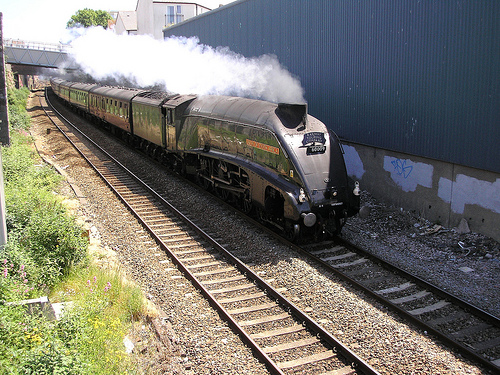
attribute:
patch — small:
[62, 314, 96, 352]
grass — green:
[8, 92, 26, 127]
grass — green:
[3, 147, 46, 200]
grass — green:
[8, 180, 75, 272]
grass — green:
[52, 286, 120, 373]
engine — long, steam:
[39, 60, 345, 240]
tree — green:
[67, 6, 110, 31]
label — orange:
[246, 137, 280, 156]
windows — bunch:
[89, 93, 130, 120]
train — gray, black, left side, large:
[50, 75, 361, 247]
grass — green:
[7, 320, 56, 354]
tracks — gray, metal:
[193, 219, 455, 372]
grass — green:
[68, 277, 142, 342]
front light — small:
[278, 189, 366, 213]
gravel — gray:
[31, 89, 496, 374]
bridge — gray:
[4, 40, 70, 89]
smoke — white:
[67, 22, 319, 114]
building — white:
[132, 1, 211, 39]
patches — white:
[343, 142, 498, 215]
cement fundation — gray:
[341, 139, 498, 240]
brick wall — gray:
[366, 117, 491, 205]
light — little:
[294, 183, 325, 225]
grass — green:
[0, 85, 137, 373]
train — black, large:
[47, 48, 377, 253]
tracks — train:
[15, 69, 499, 374]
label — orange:
[239, 131, 285, 160]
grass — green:
[40, 266, 80, 294]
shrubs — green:
[10, 191, 90, 285]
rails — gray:
[3, 37, 72, 55]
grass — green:
[1, 93, 161, 373]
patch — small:
[3, 231, 155, 371]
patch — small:
[7, 290, 118, 367]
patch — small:
[41, 326, 131, 369]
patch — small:
[40, 263, 130, 344]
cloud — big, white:
[51, 20, 311, 105]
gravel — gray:
[278, 290, 413, 364]